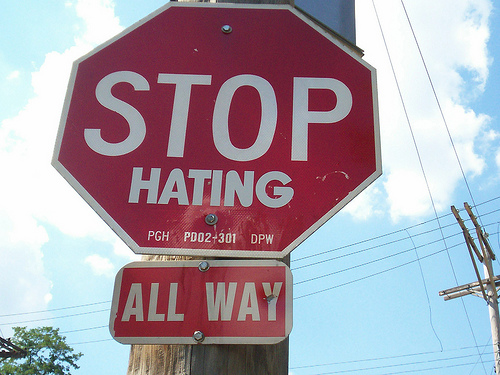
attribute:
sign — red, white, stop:
[55, 1, 393, 347]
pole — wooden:
[128, 337, 285, 374]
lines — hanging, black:
[375, 6, 492, 302]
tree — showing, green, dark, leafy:
[1, 325, 81, 373]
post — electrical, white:
[445, 199, 500, 374]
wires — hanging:
[1, 294, 116, 353]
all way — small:
[124, 278, 285, 321]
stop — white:
[86, 70, 352, 172]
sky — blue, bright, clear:
[10, 2, 497, 369]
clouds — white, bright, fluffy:
[386, 7, 483, 209]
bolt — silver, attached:
[216, 18, 242, 37]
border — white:
[128, 0, 384, 51]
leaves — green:
[18, 338, 49, 355]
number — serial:
[148, 230, 283, 250]